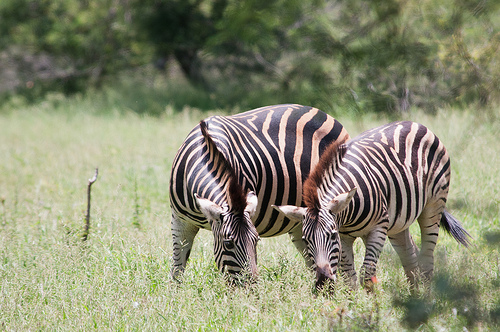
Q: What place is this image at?
A: It is at the field.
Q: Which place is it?
A: It is a field.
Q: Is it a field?
A: Yes, it is a field.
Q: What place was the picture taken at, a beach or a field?
A: It was taken at a field.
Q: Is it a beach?
A: No, it is a field.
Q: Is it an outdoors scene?
A: Yes, it is outdoors.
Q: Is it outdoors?
A: Yes, it is outdoors.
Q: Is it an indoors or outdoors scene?
A: It is outdoors.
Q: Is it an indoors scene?
A: No, it is outdoors.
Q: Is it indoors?
A: No, it is outdoors.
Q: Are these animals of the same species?
A: Yes, all the animals are zebras.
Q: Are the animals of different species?
A: No, all the animals are zebras.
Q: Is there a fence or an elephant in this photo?
A: No, there are no fences or elephants.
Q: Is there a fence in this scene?
A: No, there are no fences.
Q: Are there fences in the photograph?
A: No, there are no fences.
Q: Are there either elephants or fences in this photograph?
A: No, there are no fences or elephants.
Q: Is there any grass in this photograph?
A: Yes, there is grass.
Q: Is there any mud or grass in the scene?
A: Yes, there is grass.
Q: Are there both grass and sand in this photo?
A: No, there is grass but no sand.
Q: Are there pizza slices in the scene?
A: No, there are no pizza slices.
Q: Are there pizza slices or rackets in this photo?
A: No, there are no pizza slices or rackets.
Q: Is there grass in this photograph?
A: Yes, there is grass.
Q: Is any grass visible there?
A: Yes, there is grass.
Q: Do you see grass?
A: Yes, there is grass.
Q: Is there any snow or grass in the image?
A: Yes, there is grass.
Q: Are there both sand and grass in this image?
A: No, there is grass but no sand.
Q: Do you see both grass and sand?
A: No, there is grass but no sand.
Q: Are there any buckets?
A: No, there are no buckets.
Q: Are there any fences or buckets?
A: No, there are no buckets or fences.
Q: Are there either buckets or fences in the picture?
A: No, there are no buckets or fences.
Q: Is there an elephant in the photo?
A: No, there are no elephants.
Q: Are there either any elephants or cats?
A: No, there are no elephants or cats.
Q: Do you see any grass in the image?
A: Yes, there is grass.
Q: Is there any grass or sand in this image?
A: Yes, there is grass.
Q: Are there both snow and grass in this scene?
A: No, there is grass but no snow.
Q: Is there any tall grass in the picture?
A: Yes, there is tall grass.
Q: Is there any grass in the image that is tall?
A: Yes, there is grass that is tall.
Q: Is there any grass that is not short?
A: Yes, there is tall grass.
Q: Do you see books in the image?
A: No, there are no books.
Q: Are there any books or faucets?
A: No, there are no books or faucets.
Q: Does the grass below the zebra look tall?
A: Yes, the grass is tall.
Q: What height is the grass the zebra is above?
A: The grass is tall.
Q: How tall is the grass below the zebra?
A: The grass is tall.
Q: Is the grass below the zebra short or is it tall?
A: The grass is tall.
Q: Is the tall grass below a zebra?
A: Yes, the grass is below a zebra.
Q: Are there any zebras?
A: Yes, there is a zebra.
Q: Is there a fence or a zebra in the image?
A: Yes, there is a zebra.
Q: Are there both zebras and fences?
A: No, there is a zebra but no fences.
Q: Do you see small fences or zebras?
A: Yes, there is a small zebra.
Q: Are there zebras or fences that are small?
A: Yes, the zebra is small.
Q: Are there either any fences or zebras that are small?
A: Yes, the zebra is small.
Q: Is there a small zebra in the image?
A: Yes, there is a small zebra.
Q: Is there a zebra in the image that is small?
A: Yes, there is a zebra that is small.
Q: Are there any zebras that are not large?
A: Yes, there is a small zebra.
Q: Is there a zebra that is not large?
A: Yes, there is a small zebra.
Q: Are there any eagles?
A: No, there are no eagles.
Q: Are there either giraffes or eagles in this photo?
A: No, there are no eagles or giraffes.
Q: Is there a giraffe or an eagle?
A: No, there are no eagles or giraffes.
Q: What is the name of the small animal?
A: The animal is a zebra.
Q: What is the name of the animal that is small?
A: The animal is a zebra.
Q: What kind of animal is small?
A: The animal is a zebra.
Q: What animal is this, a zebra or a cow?
A: This is a zebra.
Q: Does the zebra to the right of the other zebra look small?
A: Yes, the zebra is small.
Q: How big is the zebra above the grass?
A: The zebra is small.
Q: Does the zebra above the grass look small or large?
A: The zebra is small.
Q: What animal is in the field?
A: The animal is a zebra.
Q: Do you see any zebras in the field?
A: Yes, there is a zebra in the field.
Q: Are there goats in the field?
A: No, there is a zebra in the field.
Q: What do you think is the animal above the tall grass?
A: The animal is a zebra.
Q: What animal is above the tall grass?
A: The animal is a zebra.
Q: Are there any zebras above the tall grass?
A: Yes, there is a zebra above the grass.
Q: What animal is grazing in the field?
A: The zebra is grazing in the field.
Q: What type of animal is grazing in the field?
A: The animal is a zebra.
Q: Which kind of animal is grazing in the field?
A: The animal is a zebra.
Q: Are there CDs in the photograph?
A: No, there are no cds.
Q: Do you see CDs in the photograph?
A: No, there are no cds.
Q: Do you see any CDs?
A: No, there are no cds.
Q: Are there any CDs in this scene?
A: No, there are no cds.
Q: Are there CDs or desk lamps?
A: No, there are no CDs or desk lamps.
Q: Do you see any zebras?
A: Yes, there is a zebra.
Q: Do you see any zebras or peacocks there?
A: Yes, there is a zebra.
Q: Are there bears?
A: No, there are no bears.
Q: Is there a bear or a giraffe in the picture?
A: No, there are no bears or giraffes.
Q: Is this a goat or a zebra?
A: This is a zebra.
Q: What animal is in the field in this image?
A: The zebra is in the field.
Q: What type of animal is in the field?
A: The animal is a zebra.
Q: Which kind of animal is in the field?
A: The animal is a zebra.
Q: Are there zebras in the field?
A: Yes, there is a zebra in the field.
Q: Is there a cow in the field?
A: No, there is a zebra in the field.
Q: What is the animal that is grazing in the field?
A: The animal is a zebra.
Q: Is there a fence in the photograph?
A: No, there are no fences.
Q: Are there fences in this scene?
A: No, there are no fences.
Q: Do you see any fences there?
A: No, there are no fences.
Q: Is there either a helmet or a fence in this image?
A: No, there are no fences or helmets.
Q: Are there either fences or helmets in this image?
A: No, there are no fences or helmets.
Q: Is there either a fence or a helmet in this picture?
A: No, there are no fences or helmets.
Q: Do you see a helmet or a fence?
A: No, there are no fences or helmets.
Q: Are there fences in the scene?
A: No, there are no fences.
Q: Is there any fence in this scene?
A: No, there are no fences.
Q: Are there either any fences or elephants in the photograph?
A: No, there are no fences or elephants.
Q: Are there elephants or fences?
A: No, there are no fences or elephants.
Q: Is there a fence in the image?
A: No, there are no fences.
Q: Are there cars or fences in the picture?
A: No, there are no fences or cars.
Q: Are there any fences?
A: No, there are no fences.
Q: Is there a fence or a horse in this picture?
A: No, there are no fences or horses.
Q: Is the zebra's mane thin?
A: No, the mane is thick.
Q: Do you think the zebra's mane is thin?
A: No, the mane is thick.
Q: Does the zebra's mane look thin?
A: No, the mane is thick.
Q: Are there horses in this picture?
A: No, there are no horses.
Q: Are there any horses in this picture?
A: No, there are no horses.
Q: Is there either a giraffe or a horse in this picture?
A: No, there are no horses or giraffes.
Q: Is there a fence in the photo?
A: No, there are no fences.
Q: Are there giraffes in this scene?
A: No, there are no giraffes.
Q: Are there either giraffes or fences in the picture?
A: No, there are no giraffes or fences.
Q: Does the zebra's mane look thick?
A: Yes, the mane is thick.